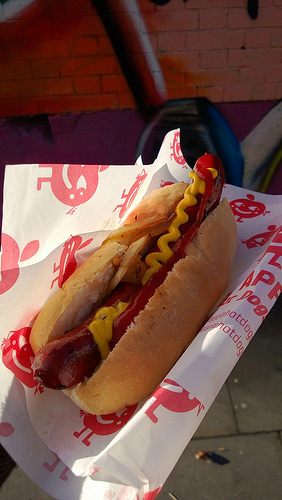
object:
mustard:
[98, 322, 108, 340]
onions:
[107, 234, 160, 289]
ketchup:
[113, 164, 212, 342]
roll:
[27, 148, 238, 420]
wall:
[1, 0, 280, 116]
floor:
[0, 298, 279, 499]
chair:
[130, 95, 244, 188]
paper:
[0, 127, 281, 500]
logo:
[228, 191, 268, 226]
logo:
[36, 163, 113, 212]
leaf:
[194, 446, 224, 461]